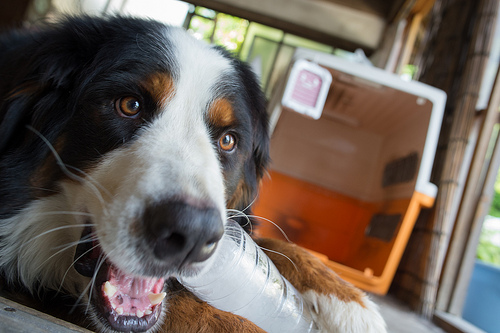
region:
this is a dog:
[9, 8, 387, 330]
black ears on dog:
[43, 2, 288, 192]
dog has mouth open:
[62, 177, 213, 327]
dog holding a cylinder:
[180, 176, 354, 330]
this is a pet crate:
[220, 19, 461, 326]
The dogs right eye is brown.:
[113, 84, 143, 122]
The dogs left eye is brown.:
[216, 121, 240, 156]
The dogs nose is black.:
[142, 195, 223, 267]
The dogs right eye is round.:
[112, 92, 147, 120]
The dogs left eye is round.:
[216, 127, 241, 153]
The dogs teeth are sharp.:
[99, 278, 166, 318]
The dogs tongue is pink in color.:
[101, 268, 172, 332]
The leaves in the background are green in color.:
[218, 17, 243, 47]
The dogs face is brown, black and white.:
[0, 6, 269, 331]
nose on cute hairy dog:
[140, 195, 229, 267]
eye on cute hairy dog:
[114, 91, 149, 118]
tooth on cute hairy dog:
[142, 289, 174, 305]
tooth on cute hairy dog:
[134, 306, 144, 318]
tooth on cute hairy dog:
[115, 302, 124, 317]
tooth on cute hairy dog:
[102, 280, 117, 297]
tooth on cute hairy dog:
[146, 303, 154, 318]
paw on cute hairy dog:
[306, 282, 386, 331]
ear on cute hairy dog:
[1, 22, 71, 147]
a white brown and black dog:
[5, 10, 272, 331]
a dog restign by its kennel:
[12, 10, 446, 331]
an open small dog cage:
[254, 45, 448, 297]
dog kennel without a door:
[264, 43, 445, 284]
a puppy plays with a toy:
[5, 17, 372, 331]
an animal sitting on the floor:
[12, 14, 382, 328]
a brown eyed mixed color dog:
[4, 14, 461, 324]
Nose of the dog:
[134, 193, 226, 277]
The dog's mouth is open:
[48, 169, 144, 329]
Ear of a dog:
[12, 13, 84, 150]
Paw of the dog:
[289, 260, 384, 329]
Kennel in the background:
[293, 40, 423, 279]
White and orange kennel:
[303, 43, 422, 268]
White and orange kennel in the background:
[286, 50, 422, 256]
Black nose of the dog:
[138, 188, 226, 266]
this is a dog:
[58, 21, 422, 293]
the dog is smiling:
[41, 50, 314, 320]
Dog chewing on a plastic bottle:
[3, 11, 394, 331]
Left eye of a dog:
[216, 123, 242, 154]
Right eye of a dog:
[112, 87, 147, 122]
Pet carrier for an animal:
[239, 40, 451, 299]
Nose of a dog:
[137, 196, 224, 266]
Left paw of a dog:
[297, 260, 390, 330]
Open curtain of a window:
[385, 2, 497, 322]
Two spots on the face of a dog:
[140, 70, 238, 126]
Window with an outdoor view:
[433, 14, 499, 331]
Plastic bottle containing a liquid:
[174, 213, 321, 330]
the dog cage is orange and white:
[240, 51, 447, 301]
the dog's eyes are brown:
[109, 83, 143, 121]